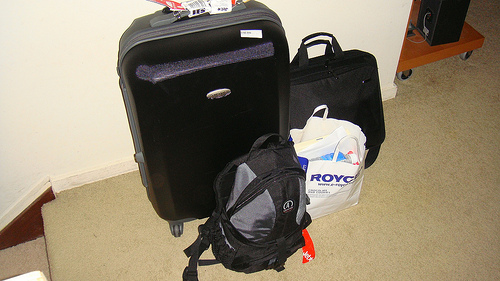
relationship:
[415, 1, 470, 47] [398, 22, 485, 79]
speaker on cart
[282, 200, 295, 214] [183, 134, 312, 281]
logo on backpack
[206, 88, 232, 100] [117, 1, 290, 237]
emblem on suitcase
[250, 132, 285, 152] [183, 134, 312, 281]
strap on backpack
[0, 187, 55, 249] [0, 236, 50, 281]
wood beside stair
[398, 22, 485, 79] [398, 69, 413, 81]
cart has a wheel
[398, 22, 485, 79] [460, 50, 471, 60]
cart has a wheel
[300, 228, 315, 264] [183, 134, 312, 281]
tag on backpack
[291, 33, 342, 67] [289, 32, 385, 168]
handle of bag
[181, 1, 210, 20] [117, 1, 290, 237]
tag on suitcase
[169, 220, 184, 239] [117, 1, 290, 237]
wheel on suitcase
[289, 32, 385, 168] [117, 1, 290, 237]
bag beside suitcase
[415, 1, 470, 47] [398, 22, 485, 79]
speaker on top of cart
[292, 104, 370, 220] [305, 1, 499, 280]
bag on carpet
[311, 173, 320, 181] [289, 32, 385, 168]
letter on bag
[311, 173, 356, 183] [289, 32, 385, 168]
letter on bag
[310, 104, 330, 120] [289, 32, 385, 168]
handle of bag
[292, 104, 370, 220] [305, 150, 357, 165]
bag full of junk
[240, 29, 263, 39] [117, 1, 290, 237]
label on suitcase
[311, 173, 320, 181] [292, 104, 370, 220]
letter on bag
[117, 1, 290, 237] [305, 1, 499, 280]
suitcase on carpet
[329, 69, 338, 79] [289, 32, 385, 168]
zipper on bag